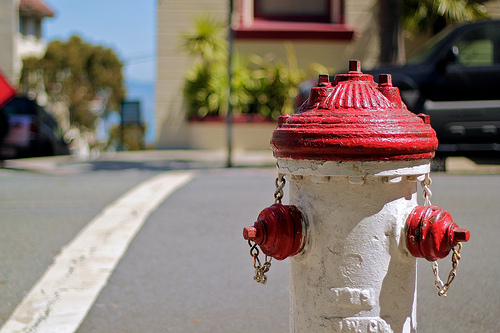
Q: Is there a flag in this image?
A: No, there are no flags.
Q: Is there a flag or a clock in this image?
A: No, there are no flags or clocks.